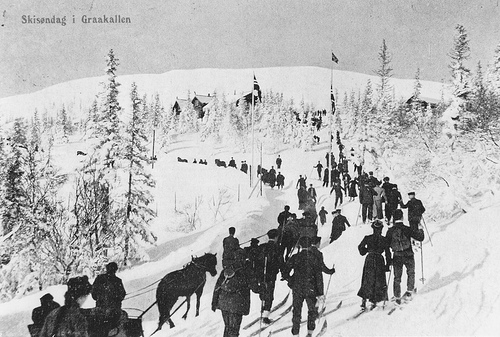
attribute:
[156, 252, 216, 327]
horse — black, walking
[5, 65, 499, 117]
snow — white, everywhere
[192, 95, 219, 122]
house — distant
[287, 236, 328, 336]
person — skiing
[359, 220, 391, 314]
lady — skiing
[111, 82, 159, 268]
tree — snow covered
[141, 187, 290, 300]
path — present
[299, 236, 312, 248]
hat — black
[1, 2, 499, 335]
photo — winter